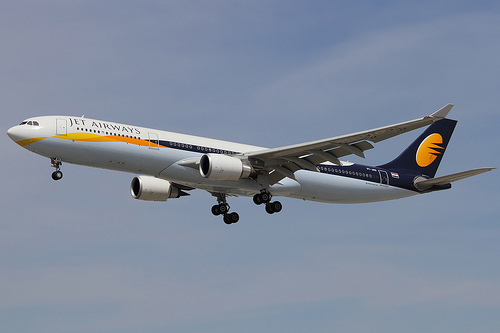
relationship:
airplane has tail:
[6, 100, 494, 229] [388, 110, 493, 202]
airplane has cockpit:
[6, 100, 494, 229] [6, 110, 48, 149]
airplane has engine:
[6, 100, 494, 229] [193, 149, 260, 182]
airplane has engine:
[6, 100, 494, 229] [129, 170, 190, 207]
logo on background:
[409, 128, 447, 168] [407, 115, 459, 179]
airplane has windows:
[6, 100, 494, 229] [72, 121, 393, 188]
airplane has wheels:
[6, 100, 494, 229] [206, 188, 286, 224]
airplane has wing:
[6, 100, 494, 229] [236, 102, 457, 182]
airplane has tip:
[6, 100, 494, 229] [5, 123, 20, 143]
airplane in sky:
[6, 100, 494, 229] [3, 2, 497, 330]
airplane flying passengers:
[6, 100, 494, 229] [16, 86, 454, 218]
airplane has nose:
[6, 100, 494, 229] [5, 123, 20, 143]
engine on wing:
[193, 149, 260, 182] [236, 102, 457, 182]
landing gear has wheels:
[208, 184, 288, 228] [206, 188, 286, 224]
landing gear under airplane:
[208, 184, 288, 228] [6, 100, 494, 229]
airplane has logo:
[6, 100, 494, 229] [409, 128, 447, 168]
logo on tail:
[409, 128, 447, 168] [388, 110, 493, 202]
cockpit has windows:
[6, 110, 48, 149] [17, 118, 40, 131]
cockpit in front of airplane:
[6, 110, 48, 149] [6, 100, 494, 229]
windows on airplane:
[72, 121, 393, 188] [6, 100, 494, 229]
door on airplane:
[51, 114, 72, 141] [6, 100, 494, 229]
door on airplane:
[372, 167, 394, 189] [6, 100, 494, 229]